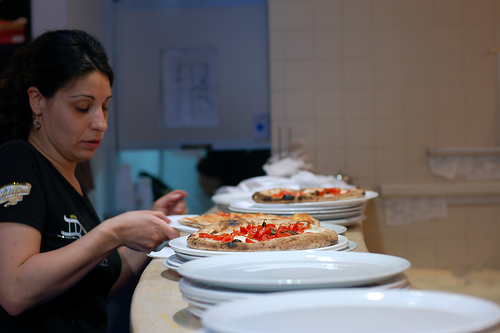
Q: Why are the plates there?
A: Hold food.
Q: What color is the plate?
A: White.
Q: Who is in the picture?
A: A woman.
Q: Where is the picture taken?
A: Restaurant.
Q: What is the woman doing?
A: Lifting plate.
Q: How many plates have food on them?
A: Three.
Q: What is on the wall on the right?
A: Food orders.